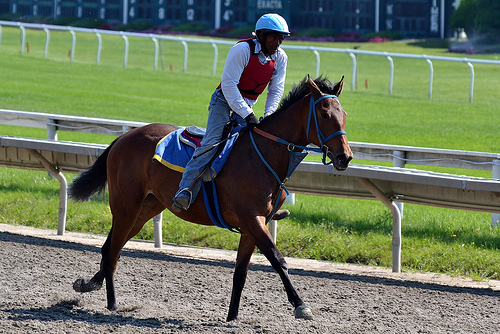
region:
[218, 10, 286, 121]
a jockey wearing a red vest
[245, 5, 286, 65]
a jockey wearing a white helmet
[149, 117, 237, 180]
a blue saddle on a horse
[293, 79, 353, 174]
a horse with a blue bridle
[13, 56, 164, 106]
cut green grass near racetrack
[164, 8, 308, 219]
a jockey riding a horse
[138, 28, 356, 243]
jockey riding a brown horse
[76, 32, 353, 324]
horse racing on track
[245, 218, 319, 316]
a horse's leg going foward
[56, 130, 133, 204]
a horse with a black tail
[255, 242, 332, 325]
horse's front right leg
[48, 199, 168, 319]
horse's back two legs while running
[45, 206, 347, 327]
horse's four legs while running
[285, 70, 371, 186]
horse with blue reins on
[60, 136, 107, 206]
horse's black tail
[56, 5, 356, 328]
horse with a jockey on its back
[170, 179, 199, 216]
stirrup for horseback riding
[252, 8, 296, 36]
white horse racing helmet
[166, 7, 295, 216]
jockey wearing a red vest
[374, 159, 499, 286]
white metal guard rail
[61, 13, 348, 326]
a man riding a horse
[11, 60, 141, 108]
a lot of grass in the field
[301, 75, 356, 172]
the head of the horse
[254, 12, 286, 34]
the horseman helmet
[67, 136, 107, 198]
wide black horse tail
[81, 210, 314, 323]
the four legs of the horse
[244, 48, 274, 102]
a protective black and red vest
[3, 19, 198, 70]
a white protective fence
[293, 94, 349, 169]
the blue break horse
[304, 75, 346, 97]
the two ears of the brown horse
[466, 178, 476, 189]
part of a wall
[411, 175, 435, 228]
part of a rail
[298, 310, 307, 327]
part of a hoof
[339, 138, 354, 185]
part of a horse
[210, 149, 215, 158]
part of a jeans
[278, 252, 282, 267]
edge of a leg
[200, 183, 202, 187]
part of a clothe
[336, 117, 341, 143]
head of a horse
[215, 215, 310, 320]
the front legs of a horse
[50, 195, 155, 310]
the rear legs of a horse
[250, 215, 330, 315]
the front leg of a horse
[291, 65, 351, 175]
the head of a horse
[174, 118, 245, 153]
the saddle on a horse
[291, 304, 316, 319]
the hoof of a horse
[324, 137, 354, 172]
the nose of a horse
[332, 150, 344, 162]
the nostril of a horse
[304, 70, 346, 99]
the ears of a horse